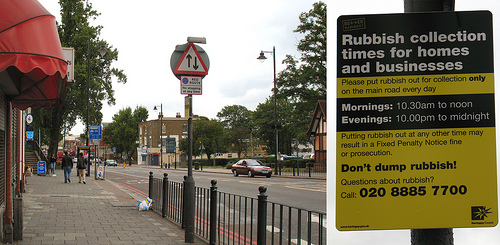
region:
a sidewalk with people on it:
[25, 113, 152, 243]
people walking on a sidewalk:
[47, 145, 107, 220]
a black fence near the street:
[146, 164, 330, 244]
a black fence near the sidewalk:
[121, 159, 318, 244]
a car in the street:
[229, 154, 271, 183]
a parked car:
[224, 153, 274, 183]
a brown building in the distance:
[131, 107, 200, 177]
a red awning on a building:
[4, 0, 61, 119]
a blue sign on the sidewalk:
[85, 121, 107, 148]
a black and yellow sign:
[333, 11, 496, 224]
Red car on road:
[223, 153, 275, 186]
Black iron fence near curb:
[140, 171, 327, 243]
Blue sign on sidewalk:
[85, 123, 107, 183]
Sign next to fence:
[150, 36, 224, 231]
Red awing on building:
[0, 24, 76, 111]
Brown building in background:
[133, 113, 200, 165]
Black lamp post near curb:
[254, 41, 283, 176]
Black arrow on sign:
[183, 49, 200, 71]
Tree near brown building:
[102, 101, 152, 166]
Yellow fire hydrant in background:
[119, 161, 129, 171]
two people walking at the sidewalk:
[52, 128, 105, 195]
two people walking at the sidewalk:
[34, 137, 126, 199]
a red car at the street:
[208, 133, 273, 195]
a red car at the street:
[211, 139, 326, 199]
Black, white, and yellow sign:
[335, 8, 499, 230]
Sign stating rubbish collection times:
[334, 10, 497, 232]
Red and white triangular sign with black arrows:
[173, 42, 210, 77]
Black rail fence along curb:
[147, 170, 324, 243]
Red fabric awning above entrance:
[1, 0, 68, 111]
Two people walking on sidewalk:
[59, 148, 89, 185]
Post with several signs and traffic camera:
[170, 35, 210, 241]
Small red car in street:
[228, 155, 272, 179]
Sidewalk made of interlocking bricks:
[23, 167, 205, 243]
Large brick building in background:
[136, 110, 201, 166]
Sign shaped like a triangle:
[175, 43, 209, 78]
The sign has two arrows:
[171, 47, 218, 76]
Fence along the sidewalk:
[142, 180, 297, 243]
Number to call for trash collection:
[343, 178, 478, 206]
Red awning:
[3, 3, 80, 100]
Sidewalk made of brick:
[32, 176, 131, 236]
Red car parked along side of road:
[224, 140, 281, 180]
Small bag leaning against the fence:
[130, 193, 156, 211]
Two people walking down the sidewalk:
[47, 133, 102, 183]